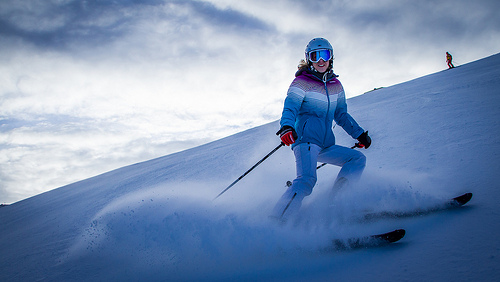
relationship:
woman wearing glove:
[258, 30, 376, 230] [350, 129, 377, 151]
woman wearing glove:
[258, 30, 376, 230] [271, 123, 304, 149]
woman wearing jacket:
[258, 30, 376, 230] [271, 64, 369, 156]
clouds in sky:
[1, 1, 500, 205] [1, 1, 498, 212]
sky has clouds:
[1, 1, 498, 212] [1, 1, 500, 205]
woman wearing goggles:
[258, 30, 376, 230] [301, 47, 338, 69]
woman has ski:
[258, 30, 376, 230] [308, 225, 410, 253]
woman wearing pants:
[258, 30, 376, 230] [278, 139, 374, 189]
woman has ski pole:
[258, 30, 376, 230] [281, 134, 368, 194]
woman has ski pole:
[258, 30, 376, 230] [216, 129, 303, 202]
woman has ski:
[258, 30, 376, 230] [339, 190, 478, 233]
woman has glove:
[258, 30, 376, 230] [350, 129, 377, 151]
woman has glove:
[258, 30, 376, 230] [271, 123, 304, 149]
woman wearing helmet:
[258, 30, 376, 230] [302, 34, 340, 65]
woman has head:
[258, 30, 376, 230] [294, 37, 338, 77]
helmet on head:
[302, 34, 340, 65] [294, 37, 338, 77]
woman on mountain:
[258, 30, 376, 230] [3, 50, 500, 281]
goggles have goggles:
[301, 47, 338, 69] [308, 48, 333, 63]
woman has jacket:
[258, 30, 376, 230] [271, 64, 369, 156]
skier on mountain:
[441, 47, 460, 70] [3, 50, 500, 281]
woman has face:
[258, 30, 376, 230] [311, 57, 333, 76]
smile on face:
[315, 62, 328, 70] [311, 57, 333, 76]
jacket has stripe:
[271, 64, 369, 156] [284, 84, 344, 109]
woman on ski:
[258, 30, 376, 230] [308, 225, 410, 253]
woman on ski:
[258, 30, 376, 230] [339, 190, 478, 233]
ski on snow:
[308, 225, 410, 253] [3, 53, 500, 280]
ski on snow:
[339, 190, 478, 233] [3, 53, 500, 280]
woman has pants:
[258, 30, 376, 230] [278, 139, 374, 189]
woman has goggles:
[258, 30, 376, 230] [301, 47, 338, 69]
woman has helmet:
[258, 30, 376, 230] [302, 34, 340, 65]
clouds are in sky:
[1, 1, 500, 205] [1, 1, 498, 212]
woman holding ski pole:
[258, 30, 376, 230] [281, 134, 368, 194]